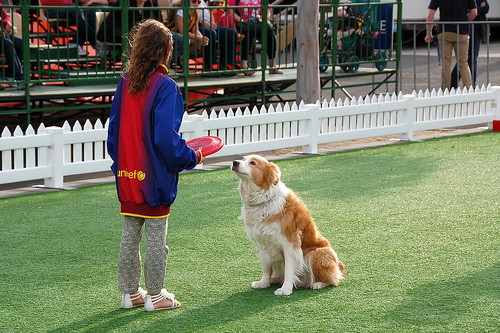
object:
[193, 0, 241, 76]
spectators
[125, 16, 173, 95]
hair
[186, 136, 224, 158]
frisbee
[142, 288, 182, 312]
sandal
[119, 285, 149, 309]
sandal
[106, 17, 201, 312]
girl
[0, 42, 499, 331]
ground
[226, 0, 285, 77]
people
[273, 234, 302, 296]
leg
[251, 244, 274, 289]
leg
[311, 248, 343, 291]
leg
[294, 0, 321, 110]
post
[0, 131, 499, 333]
grass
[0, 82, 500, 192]
fence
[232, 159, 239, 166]
nose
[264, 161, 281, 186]
ear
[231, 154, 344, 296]
dog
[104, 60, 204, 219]
jacket